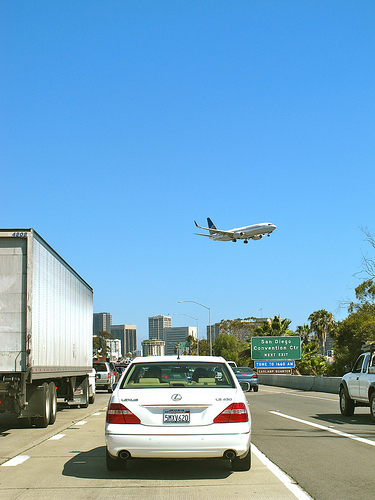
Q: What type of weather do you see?
A: It is cloudless.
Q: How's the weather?
A: It is cloudless.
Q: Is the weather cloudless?
A: Yes, it is cloudless.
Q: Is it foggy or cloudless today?
A: It is cloudless.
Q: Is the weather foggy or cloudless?
A: It is cloudless.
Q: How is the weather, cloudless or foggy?
A: It is cloudless.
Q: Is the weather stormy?
A: No, it is cloudless.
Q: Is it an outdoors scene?
A: Yes, it is outdoors.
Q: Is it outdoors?
A: Yes, it is outdoors.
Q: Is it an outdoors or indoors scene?
A: It is outdoors.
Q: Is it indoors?
A: No, it is outdoors.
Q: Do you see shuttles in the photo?
A: No, there are no shuttles.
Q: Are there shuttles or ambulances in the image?
A: No, there are no shuttles or ambulances.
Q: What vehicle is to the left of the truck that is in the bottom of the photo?
A: The vehicle is a car.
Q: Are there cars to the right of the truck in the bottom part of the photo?
A: No, the car is to the left of the truck.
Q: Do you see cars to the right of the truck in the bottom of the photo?
A: No, the car is to the left of the truck.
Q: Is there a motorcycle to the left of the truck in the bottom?
A: No, there is a car to the left of the truck.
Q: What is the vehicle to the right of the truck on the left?
A: The vehicle is a car.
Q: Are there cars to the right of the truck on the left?
A: Yes, there is a car to the right of the truck.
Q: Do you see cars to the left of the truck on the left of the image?
A: No, the car is to the right of the truck.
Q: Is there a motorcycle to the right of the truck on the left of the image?
A: No, there is a car to the right of the truck.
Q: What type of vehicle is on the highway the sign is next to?
A: The vehicle is a car.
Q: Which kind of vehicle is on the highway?
A: The vehicle is a car.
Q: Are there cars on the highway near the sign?
A: Yes, there is a car on the highway.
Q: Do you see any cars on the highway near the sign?
A: Yes, there is a car on the highway.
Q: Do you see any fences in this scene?
A: No, there are no fences.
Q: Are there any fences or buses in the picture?
A: No, there are no fences or buses.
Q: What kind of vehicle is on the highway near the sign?
A: The vehicle is a car.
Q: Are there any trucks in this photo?
A: Yes, there is a truck.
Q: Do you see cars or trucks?
A: Yes, there is a truck.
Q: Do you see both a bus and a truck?
A: No, there is a truck but no buses.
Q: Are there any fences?
A: No, there are no fences.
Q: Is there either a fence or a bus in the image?
A: No, there are no fences or buses.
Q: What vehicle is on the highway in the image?
A: The vehicle is a truck.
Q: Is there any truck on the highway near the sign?
A: Yes, there is a truck on the highway.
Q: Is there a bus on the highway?
A: No, there is a truck on the highway.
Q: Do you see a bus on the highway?
A: No, there is a truck on the highway.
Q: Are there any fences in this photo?
A: No, there are no fences.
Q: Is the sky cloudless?
A: Yes, the sky is cloudless.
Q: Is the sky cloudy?
A: No, the sky is cloudless.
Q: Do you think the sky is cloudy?
A: No, the sky is cloudless.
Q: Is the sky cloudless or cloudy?
A: The sky is cloudless.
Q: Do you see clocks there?
A: No, there are no clocks.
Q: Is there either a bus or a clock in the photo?
A: No, there are no clocks or buses.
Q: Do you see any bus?
A: No, there are no buses.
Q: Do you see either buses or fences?
A: No, there are no buses or fences.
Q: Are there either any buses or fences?
A: No, there are no buses or fences.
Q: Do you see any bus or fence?
A: No, there are no buses or fences.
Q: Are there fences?
A: No, there are no fences.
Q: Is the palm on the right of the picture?
A: Yes, the palm is on the right of the image.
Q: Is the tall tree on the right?
A: Yes, the palm is on the right of the image.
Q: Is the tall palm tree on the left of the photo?
A: No, the palm tree is on the right of the image.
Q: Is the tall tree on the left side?
A: No, the palm tree is on the right of the image.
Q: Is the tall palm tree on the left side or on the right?
A: The palm is on the right of the image.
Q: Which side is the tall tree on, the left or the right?
A: The palm is on the right of the image.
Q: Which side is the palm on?
A: The palm is on the right of the image.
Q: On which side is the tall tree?
A: The palm is on the right of the image.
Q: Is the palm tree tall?
A: Yes, the palm tree is tall.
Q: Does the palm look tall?
A: Yes, the palm is tall.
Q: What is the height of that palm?
A: The palm is tall.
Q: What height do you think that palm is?
A: The palm is tall.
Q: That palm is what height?
A: The palm is tall.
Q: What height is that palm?
A: The palm is tall.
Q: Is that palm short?
A: No, the palm is tall.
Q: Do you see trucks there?
A: Yes, there is a truck.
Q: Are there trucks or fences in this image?
A: Yes, there is a truck.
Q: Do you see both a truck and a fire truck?
A: No, there is a truck but no fire trucks.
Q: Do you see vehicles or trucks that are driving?
A: Yes, the truck is driving.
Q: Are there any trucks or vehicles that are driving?
A: Yes, the truck is driving.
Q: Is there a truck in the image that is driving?
A: Yes, there is a truck that is driving.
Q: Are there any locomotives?
A: No, there are no locomotives.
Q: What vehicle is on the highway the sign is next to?
A: The vehicle is a truck.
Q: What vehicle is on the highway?
A: The vehicle is a truck.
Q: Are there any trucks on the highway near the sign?
A: Yes, there is a truck on the highway.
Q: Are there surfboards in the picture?
A: No, there are no surfboards.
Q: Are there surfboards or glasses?
A: No, there are no surfboards or glasses.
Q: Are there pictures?
A: No, there are no pictures.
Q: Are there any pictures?
A: No, there are no pictures.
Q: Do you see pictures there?
A: No, there are no pictures.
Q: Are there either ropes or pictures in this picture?
A: No, there are no pictures or ropes.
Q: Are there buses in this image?
A: No, there are no buses.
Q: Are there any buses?
A: No, there are no buses.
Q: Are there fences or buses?
A: No, there are no buses or fences.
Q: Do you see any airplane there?
A: Yes, there is an airplane.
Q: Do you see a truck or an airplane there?
A: Yes, there is an airplane.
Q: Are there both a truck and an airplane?
A: Yes, there are both an airplane and a truck.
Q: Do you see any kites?
A: No, there are no kites.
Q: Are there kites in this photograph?
A: No, there are no kites.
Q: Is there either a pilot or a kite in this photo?
A: No, there are no kites or pilots.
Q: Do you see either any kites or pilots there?
A: No, there are no kites or pilots.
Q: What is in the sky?
A: The plane is in the sky.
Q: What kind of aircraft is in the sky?
A: The aircraft is an airplane.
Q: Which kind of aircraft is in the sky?
A: The aircraft is an airplane.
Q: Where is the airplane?
A: The airplane is in the sky.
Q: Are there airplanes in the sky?
A: Yes, there is an airplane in the sky.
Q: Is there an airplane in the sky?
A: Yes, there is an airplane in the sky.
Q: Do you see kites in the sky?
A: No, there is an airplane in the sky.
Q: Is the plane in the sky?
A: Yes, the plane is in the sky.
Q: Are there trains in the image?
A: No, there are no trains.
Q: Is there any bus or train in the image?
A: No, there are no trains or buses.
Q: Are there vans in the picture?
A: No, there are no vans.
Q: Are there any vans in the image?
A: No, there are no vans.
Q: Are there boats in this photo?
A: No, there are no boats.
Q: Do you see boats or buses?
A: No, there are no boats or buses.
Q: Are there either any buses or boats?
A: No, there are no boats or buses.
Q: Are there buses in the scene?
A: No, there are no buses.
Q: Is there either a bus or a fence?
A: No, there are no buses or fences.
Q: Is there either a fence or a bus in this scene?
A: No, there are no buses or fences.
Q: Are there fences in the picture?
A: No, there are no fences.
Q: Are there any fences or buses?
A: No, there are no fences or buses.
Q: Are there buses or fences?
A: No, there are no fences or buses.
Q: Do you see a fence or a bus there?
A: No, there are no fences or buses.